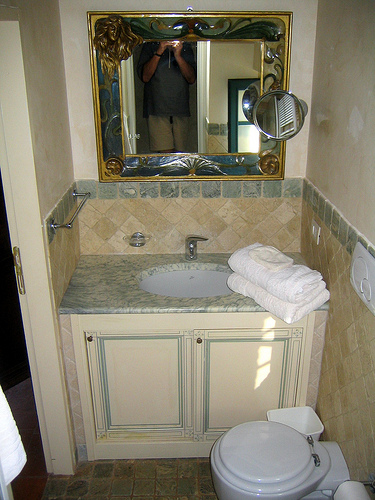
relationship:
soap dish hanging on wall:
[122, 231, 151, 245] [72, 180, 303, 253]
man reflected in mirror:
[134, 40, 199, 154] [86, 12, 293, 182]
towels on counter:
[227, 242, 330, 323] [57, 252, 329, 314]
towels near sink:
[227, 242, 330, 323] [137, 260, 241, 298]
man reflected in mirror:
[141, 40, 196, 151] [86, 12, 293, 182]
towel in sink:
[227, 241, 334, 324] [137, 261, 235, 297]